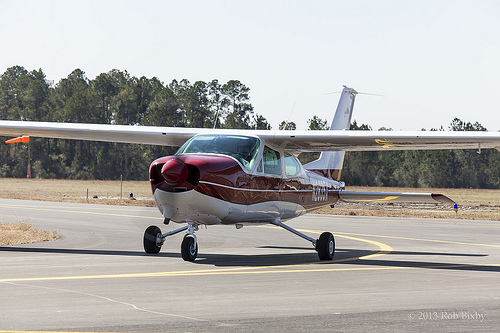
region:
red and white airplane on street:
[26, 105, 388, 262]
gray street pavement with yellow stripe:
[16, 267, 79, 293]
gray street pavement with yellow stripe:
[76, 270, 126, 284]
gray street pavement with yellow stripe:
[138, 268, 175, 283]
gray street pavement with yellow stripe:
[181, 267, 224, 284]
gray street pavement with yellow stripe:
[241, 257, 290, 286]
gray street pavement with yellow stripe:
[282, 254, 313, 280]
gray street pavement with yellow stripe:
[347, 246, 366, 274]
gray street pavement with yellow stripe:
[361, 227, 387, 262]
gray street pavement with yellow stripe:
[79, 208, 124, 226]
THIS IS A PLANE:
[1, 79, 499, 268]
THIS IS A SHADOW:
[1, 243, 498, 282]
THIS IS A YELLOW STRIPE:
[1, 202, 400, 290]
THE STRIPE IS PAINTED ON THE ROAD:
[1, 202, 403, 294]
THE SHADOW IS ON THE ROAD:
[0, 240, 498, 281]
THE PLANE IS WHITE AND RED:
[1, 78, 498, 265]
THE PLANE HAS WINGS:
[1, 110, 499, 158]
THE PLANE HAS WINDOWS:
[168, 129, 315, 193]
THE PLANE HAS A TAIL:
[308, 83, 361, 195]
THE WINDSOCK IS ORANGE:
[3, 131, 30, 149]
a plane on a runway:
[1, 82, 498, 262]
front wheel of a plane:
[180, 233, 198, 260]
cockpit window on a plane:
[177, 130, 255, 162]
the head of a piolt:
[235, 140, 250, 155]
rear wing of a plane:
[335, 185, 457, 208]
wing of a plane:
[0, 114, 498, 150]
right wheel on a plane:
[144, 225, 160, 250]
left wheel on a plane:
[316, 232, 336, 262]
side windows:
[258, 145, 300, 175]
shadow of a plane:
[1, 242, 498, 273]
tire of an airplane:
[312, 230, 339, 264]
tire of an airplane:
[179, 232, 199, 264]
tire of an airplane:
[139, 220, 169, 255]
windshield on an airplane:
[172, 129, 264, 164]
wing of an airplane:
[0, 109, 195, 147]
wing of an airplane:
[267, 121, 498, 163]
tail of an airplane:
[297, 82, 382, 189]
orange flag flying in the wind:
[2, 131, 36, 149]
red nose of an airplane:
[152, 155, 203, 192]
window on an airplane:
[255, 145, 286, 175]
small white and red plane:
[14, 62, 481, 274]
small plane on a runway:
[36, 73, 459, 276]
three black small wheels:
[126, 228, 358, 274]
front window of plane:
[181, 127, 244, 162]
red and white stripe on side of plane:
[187, 178, 341, 204]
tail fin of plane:
[324, 85, 361, 132]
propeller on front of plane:
[144, 143, 201, 195]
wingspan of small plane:
[0, 120, 478, 138]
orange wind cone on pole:
[6, 137, 46, 184]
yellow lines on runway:
[0, 268, 185, 301]